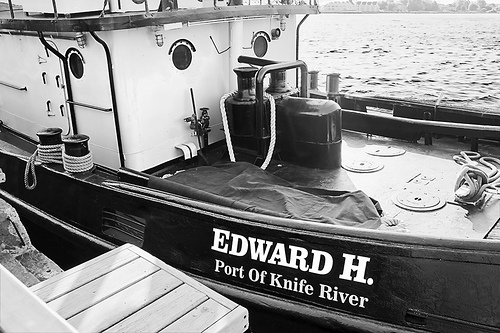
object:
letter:
[338, 251, 372, 285]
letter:
[307, 245, 334, 277]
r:
[287, 245, 312, 272]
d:
[228, 232, 252, 265]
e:
[208, 219, 235, 255]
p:
[211, 256, 225, 275]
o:
[224, 264, 233, 276]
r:
[231, 266, 239, 279]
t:
[238, 265, 247, 282]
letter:
[296, 272, 309, 294]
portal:
[167, 40, 197, 75]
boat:
[0, 6, 499, 326]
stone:
[30, 237, 252, 332]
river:
[362, 11, 499, 90]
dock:
[5, 205, 269, 332]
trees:
[479, 1, 498, 14]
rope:
[60, 135, 95, 180]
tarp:
[137, 151, 384, 231]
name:
[211, 224, 380, 314]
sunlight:
[344, 16, 443, 83]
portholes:
[55, 34, 93, 83]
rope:
[219, 84, 280, 165]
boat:
[323, 3, 384, 17]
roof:
[0, 0, 321, 32]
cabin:
[0, 4, 313, 174]